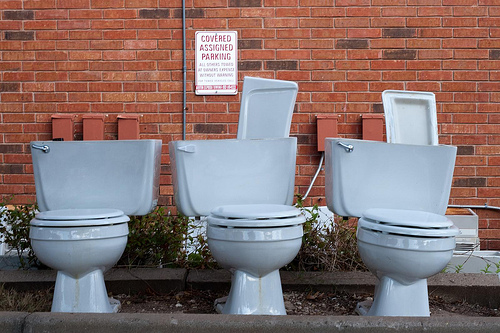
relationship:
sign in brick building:
[193, 26, 237, 95] [1, 2, 498, 249]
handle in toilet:
[332, 138, 351, 155] [322, 131, 464, 321]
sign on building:
[193, 26, 237, 95] [1, 0, 496, 267]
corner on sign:
[224, 31, 244, 55] [191, 27, 239, 95]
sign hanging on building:
[185, 25, 247, 100] [1, 0, 496, 267]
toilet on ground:
[25, 133, 165, 313] [313, 298, 353, 331]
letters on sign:
[199, 32, 206, 44] [192, 25, 242, 97]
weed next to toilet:
[0, 192, 42, 276] [165, 70, 313, 314]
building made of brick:
[294, 17, 399, 73] [53, 20, 90, 30]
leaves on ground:
[148, 235, 176, 259] [470, 295, 483, 305]